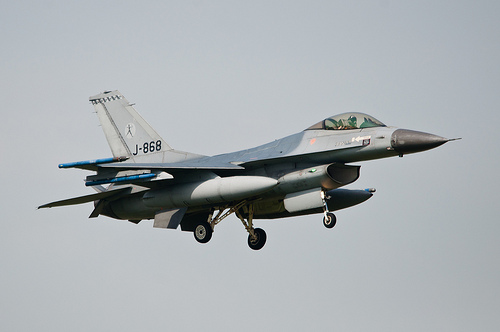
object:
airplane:
[36, 89, 462, 250]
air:
[0, 1, 500, 331]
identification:
[132, 140, 163, 156]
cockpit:
[305, 111, 387, 130]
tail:
[35, 87, 211, 231]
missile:
[90, 174, 280, 221]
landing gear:
[193, 197, 269, 250]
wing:
[57, 154, 245, 186]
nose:
[391, 127, 461, 158]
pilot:
[347, 114, 357, 128]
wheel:
[193, 221, 213, 244]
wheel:
[248, 227, 268, 250]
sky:
[1, 1, 499, 330]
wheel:
[322, 212, 337, 229]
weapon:
[58, 155, 130, 169]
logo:
[124, 123, 136, 139]